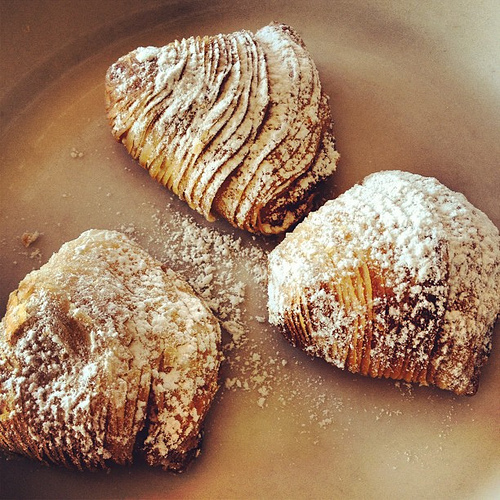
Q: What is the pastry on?
A: Beige Table.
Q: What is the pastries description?
A: Cone shaped.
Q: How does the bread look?
A: It looks red.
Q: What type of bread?
A: Red with sugar.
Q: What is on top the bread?
A: Sweet sugar.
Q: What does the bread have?
A: Sugar on top.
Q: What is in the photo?
A: Food.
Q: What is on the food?
A: Powdered sugar.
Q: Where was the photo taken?
A: Above food.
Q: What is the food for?
A: Eating.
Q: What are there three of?
A: Pieces of food.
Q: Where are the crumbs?
A: Next to the food.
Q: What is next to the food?
A: Crumbs.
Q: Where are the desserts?
A: On plate.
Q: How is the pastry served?
A: With sugar.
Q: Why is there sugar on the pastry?
A: Sweeten.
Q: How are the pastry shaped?
A: Like shell.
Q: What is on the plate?
A: Italian dessert.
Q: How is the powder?
A: Scattered.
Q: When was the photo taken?
A: Meal time.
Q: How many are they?
A: 3.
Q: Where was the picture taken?
A: At a bakery.